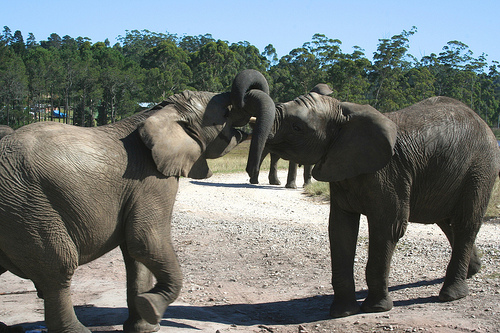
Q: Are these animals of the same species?
A: Yes, all the animals are elephants.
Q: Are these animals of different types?
A: No, all the animals are elephants.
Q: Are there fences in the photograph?
A: No, there are no fences.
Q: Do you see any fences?
A: No, there are no fences.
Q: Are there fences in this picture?
A: No, there are no fences.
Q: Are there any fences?
A: No, there are no fences.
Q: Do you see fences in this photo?
A: No, there are no fences.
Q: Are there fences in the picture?
A: No, there are no fences.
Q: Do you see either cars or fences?
A: No, there are no fences or cars.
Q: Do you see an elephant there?
A: Yes, there is an elephant.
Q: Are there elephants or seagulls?
A: Yes, there is an elephant.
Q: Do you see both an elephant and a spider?
A: No, there is an elephant but no spiders.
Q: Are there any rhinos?
A: No, there are no rhinos.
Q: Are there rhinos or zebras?
A: No, there are no rhinos or zebras.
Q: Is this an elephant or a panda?
A: This is an elephant.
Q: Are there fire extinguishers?
A: No, there are no fire extinguishers.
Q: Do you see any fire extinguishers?
A: No, there are no fire extinguishers.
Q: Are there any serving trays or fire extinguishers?
A: No, there are no fire extinguishers or serving trays.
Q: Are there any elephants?
A: Yes, there is an elephant.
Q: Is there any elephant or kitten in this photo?
A: Yes, there is an elephant.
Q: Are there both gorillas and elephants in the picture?
A: No, there is an elephant but no gorillas.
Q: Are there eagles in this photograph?
A: No, there are no eagles.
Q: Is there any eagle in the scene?
A: No, there are no eagles.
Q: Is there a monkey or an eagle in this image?
A: No, there are no eagles or monkeys.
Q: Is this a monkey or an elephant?
A: This is an elephant.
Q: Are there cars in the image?
A: No, there are no cars.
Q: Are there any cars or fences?
A: No, there are no cars or fences.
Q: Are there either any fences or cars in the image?
A: No, there are no cars or fences.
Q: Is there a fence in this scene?
A: No, there are no fences.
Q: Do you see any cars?
A: No, there are no cars.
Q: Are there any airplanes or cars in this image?
A: No, there are no cars or airplanes.